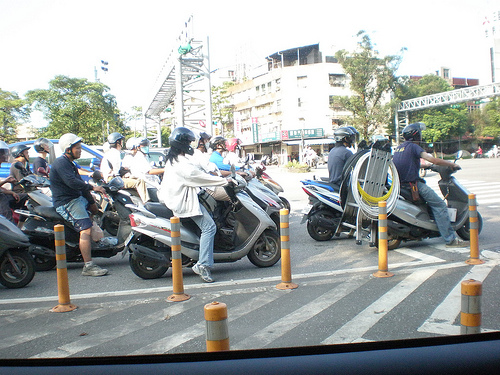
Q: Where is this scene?
A: A city street.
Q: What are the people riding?
A: Scooters.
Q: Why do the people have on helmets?
A: To protect their heads.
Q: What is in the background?
A: Buildings.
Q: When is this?
A: Daytime.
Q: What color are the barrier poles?
A: Yellow and silver.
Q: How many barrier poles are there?
A: Seven.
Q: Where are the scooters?
A: In the street.